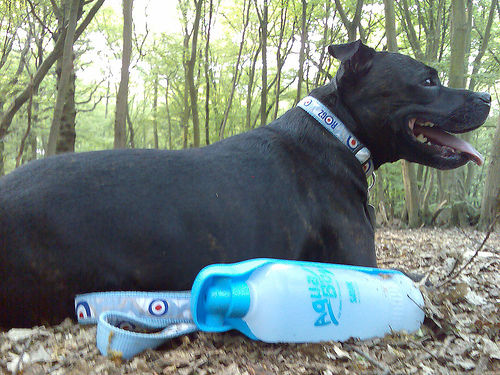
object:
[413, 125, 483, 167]
tongue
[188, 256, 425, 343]
bottle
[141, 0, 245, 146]
green trees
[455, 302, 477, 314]
leaf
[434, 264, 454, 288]
leaf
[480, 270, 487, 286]
leaf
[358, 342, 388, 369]
leaf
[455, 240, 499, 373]
ground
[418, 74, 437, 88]
eye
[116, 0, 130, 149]
tree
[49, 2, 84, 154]
tree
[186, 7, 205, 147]
tree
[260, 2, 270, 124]
tree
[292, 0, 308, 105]
tree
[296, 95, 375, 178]
collar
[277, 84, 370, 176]
neck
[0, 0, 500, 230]
woodland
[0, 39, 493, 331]
dog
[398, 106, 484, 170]
mouth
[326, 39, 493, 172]
head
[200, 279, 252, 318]
top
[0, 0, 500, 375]
photo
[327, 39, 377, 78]
ear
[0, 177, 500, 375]
foreground